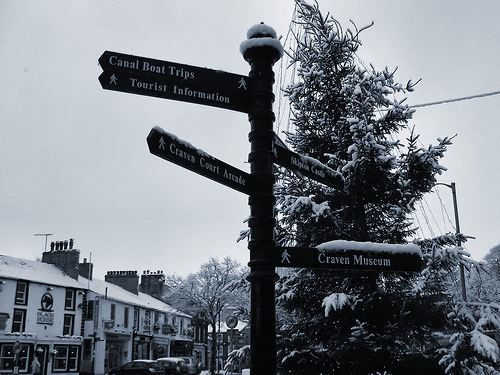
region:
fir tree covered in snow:
[269, 0, 494, 371]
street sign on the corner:
[99, 22, 425, 369]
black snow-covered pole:
[245, 27, 278, 374]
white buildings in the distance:
[2, 255, 207, 374]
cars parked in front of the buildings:
[122, 355, 199, 373]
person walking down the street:
[30, 356, 41, 371]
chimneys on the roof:
[42, 240, 163, 295]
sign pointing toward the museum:
[278, 246, 423, 273]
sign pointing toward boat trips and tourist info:
[96, 50, 250, 110]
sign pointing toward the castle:
[274, 143, 344, 187]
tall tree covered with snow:
[300, 8, 454, 268]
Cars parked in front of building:
[112, 341, 214, 373]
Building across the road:
[16, 270, 231, 358]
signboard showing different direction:
[86, 38, 424, 301]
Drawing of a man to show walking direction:
[281, 248, 292, 267]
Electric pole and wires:
[379, 123, 497, 310]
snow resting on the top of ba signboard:
[316, 238, 438, 251]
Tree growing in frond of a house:
[178, 267, 243, 364]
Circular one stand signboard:
[223, 308, 240, 370]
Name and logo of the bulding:
[38, 291, 62, 331]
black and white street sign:
[100, 50, 254, 110]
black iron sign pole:
[248, 22, 275, 374]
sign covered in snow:
[280, 236, 425, 274]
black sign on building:
[35, 292, 56, 329]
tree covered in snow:
[253, 6, 488, 368]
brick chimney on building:
[43, 239, 80, 281]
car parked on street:
[116, 358, 166, 373]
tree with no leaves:
[186, 258, 247, 370]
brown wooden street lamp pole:
[450, 181, 468, 306]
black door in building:
[32, 346, 49, 371]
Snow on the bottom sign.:
[279, 232, 434, 279]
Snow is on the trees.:
[299, 54, 421, 229]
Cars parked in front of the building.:
[105, 357, 206, 372]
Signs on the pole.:
[110, 39, 260, 203]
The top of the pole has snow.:
[231, 21, 303, 63]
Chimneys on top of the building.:
[38, 236, 108, 283]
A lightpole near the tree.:
[420, 183, 486, 309]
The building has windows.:
[3, 284, 32, 340]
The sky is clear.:
[36, 53, 148, 216]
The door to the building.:
[51, 342, 78, 374]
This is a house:
[0, 235, 242, 371]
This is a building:
[0, 230, 215, 370]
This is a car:
[110, 358, 165, 374]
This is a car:
[151, 356, 189, 373]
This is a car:
[176, 357, 206, 374]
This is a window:
[12, 278, 32, 308]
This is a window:
[8, 306, 27, 336]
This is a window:
[61, 286, 77, 312]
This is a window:
[58, 313, 75, 340]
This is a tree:
[286, 1, 483, 371]